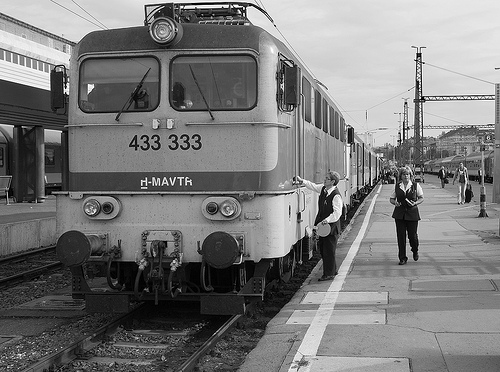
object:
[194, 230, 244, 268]
ram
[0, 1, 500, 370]
photo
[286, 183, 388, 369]
white line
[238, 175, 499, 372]
platform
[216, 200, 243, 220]
lights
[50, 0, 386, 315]
train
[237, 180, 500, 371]
sidewalk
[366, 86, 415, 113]
power lines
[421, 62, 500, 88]
power lines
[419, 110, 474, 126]
power lines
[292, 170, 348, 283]
woman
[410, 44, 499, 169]
frame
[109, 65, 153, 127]
windshield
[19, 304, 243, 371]
track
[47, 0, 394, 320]
train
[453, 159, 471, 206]
person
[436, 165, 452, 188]
person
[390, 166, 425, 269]
person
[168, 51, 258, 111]
frontwindow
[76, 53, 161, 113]
frontwindow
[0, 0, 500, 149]
sky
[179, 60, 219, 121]
wipers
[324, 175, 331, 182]
glasses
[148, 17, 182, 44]
light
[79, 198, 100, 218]
light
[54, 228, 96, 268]
safety ram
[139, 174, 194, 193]
writing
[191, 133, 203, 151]
numbers